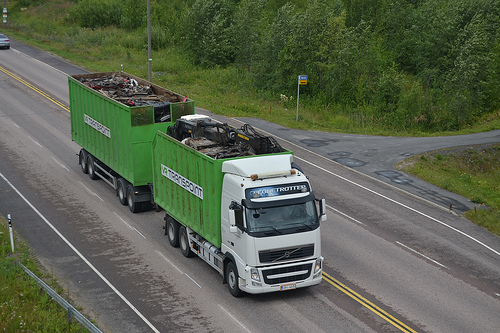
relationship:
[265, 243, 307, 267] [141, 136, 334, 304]
grill on truck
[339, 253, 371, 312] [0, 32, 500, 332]
lines on highway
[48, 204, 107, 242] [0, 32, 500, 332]
water on highway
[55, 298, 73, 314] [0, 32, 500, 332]
railing near highway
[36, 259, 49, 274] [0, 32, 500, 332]
weeds near highway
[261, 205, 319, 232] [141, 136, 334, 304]
windshield on truck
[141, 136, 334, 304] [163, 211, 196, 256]
truck has wheel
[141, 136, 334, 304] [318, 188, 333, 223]
truck has mirror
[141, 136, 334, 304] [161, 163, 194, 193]
truck has word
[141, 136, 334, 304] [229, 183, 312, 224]
truck has cab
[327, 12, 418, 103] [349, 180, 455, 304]
tree beside highway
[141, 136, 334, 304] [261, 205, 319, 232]
truck has windshield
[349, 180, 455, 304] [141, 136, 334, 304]
highway near truck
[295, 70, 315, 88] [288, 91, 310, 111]
sign on pole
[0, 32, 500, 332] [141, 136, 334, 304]
highway has truck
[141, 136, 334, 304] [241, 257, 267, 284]
truck has headlight